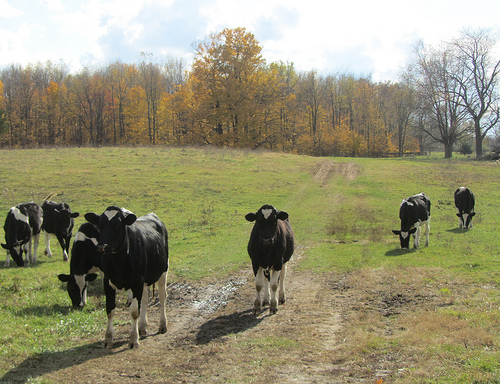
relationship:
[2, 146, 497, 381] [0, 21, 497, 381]
grass on pasture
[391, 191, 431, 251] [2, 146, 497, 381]
cow eating grass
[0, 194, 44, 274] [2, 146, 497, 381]
cow eating grass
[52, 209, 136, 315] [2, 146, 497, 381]
cow eating grass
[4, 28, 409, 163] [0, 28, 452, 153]
trees with leaves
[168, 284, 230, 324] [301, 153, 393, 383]
mud pool on track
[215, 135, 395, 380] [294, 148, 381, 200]
passage with tracks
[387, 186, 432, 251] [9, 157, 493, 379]
cow grazing in field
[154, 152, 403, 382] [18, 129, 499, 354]
tracks in grass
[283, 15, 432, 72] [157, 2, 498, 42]
sky next to clouds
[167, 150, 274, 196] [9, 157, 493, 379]
green grass in field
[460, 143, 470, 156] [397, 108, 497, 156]
green tree in distance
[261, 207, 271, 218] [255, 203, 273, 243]
spot in face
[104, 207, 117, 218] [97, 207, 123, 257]
spot in face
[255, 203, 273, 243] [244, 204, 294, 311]
face on cow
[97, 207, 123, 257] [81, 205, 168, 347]
face on cow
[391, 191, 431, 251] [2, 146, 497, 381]
cow grazing on grass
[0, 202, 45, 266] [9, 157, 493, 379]
cow in field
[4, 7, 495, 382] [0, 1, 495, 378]
picture taken outdoors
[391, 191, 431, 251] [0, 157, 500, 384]
cow on a field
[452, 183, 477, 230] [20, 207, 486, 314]
cows are walking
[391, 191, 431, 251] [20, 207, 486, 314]
cow are walking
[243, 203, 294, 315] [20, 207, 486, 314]
cow are walking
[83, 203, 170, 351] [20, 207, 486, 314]
cows are walking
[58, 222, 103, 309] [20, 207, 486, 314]
cow are walking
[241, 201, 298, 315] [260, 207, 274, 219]
cow has a triangle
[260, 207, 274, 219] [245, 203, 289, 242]
triangle on head